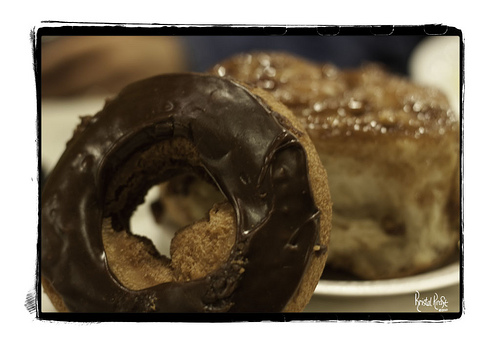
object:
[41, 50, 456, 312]
two donuts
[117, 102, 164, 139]
glazed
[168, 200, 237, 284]
bulge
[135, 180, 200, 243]
hole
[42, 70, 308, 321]
frosting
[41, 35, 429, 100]
arm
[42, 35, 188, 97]
hand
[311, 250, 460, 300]
plate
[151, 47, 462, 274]
cinnamon bun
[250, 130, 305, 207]
swirl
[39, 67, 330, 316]
donut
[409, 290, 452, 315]
name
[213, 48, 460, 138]
glaze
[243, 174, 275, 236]
chocolate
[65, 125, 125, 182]
light reflecting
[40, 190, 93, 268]
chocolate frosting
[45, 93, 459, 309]
table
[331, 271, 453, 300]
edge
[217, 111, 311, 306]
bumps